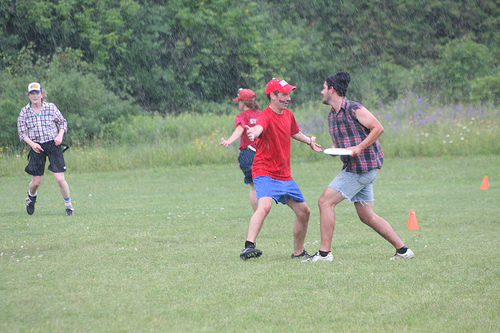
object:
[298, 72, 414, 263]
man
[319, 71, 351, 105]
head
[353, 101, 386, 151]
arm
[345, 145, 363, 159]
hand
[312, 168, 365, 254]
leg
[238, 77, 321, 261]
man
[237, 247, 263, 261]
shoe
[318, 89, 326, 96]
nose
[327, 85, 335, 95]
ear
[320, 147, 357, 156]
frisbee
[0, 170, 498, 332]
grass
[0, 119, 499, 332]
ground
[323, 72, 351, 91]
hat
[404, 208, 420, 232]
cones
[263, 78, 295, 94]
hat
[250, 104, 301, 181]
shirt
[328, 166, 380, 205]
shorts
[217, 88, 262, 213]
woman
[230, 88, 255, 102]
hat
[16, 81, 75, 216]
man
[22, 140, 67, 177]
shorts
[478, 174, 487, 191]
cone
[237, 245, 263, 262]
foot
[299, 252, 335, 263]
foot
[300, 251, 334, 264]
shoe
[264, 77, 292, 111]
head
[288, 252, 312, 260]
shoes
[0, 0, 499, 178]
background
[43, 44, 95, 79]
trees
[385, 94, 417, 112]
flowers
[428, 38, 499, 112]
tree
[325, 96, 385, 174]
shirt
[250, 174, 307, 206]
shorts